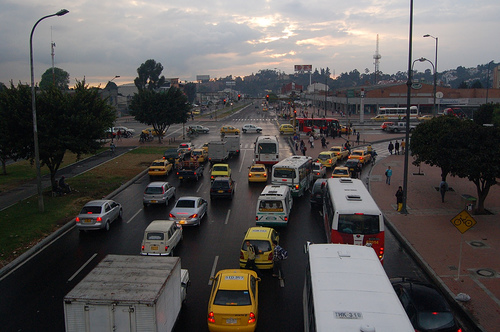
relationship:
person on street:
[268, 235, 287, 286] [1, 97, 483, 330]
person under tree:
[54, 177, 76, 200] [16, 82, 113, 164]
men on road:
[243, 239, 258, 271] [0, 100, 468, 329]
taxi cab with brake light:
[202, 263, 264, 328] [204, 308, 217, 327]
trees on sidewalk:
[412, 93, 496, 212] [410, 179, 493, 288]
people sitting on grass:
[45, 171, 76, 199] [76, 173, 103, 195]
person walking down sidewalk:
[384, 161, 392, 186] [365, 144, 495, 327]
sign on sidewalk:
[452, 209, 475, 232] [373, 140, 499, 329]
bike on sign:
[450, 213, 477, 235] [449, 209, 479, 235]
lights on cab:
[203, 305, 259, 325] [188, 207, 300, 324]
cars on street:
[92, 160, 444, 322] [176, 130, 275, 327]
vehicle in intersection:
[255, 181, 295, 228] [129, 104, 359, 232]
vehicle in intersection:
[171, 193, 206, 224] [129, 104, 359, 232]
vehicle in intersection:
[73, 197, 127, 232] [129, 104, 359, 232]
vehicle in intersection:
[248, 162, 266, 181] [129, 104, 359, 232]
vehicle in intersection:
[210, 163, 230, 184] [129, 104, 359, 232]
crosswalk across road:
[170, 141, 297, 159] [178, 122, 308, 287]